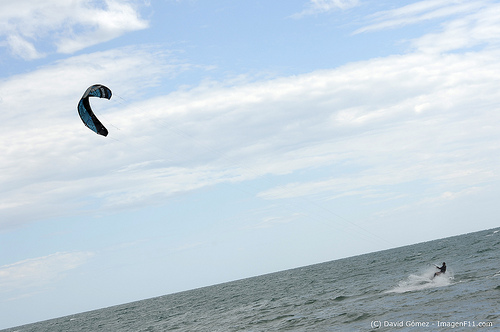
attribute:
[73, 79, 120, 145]
parasail — blue, black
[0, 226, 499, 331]
water — calm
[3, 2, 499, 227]
sky — blue, cloudy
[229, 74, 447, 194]
clouds — white, whtie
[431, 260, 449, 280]
person — parasurfing, kiteboarding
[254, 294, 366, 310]
waves — small